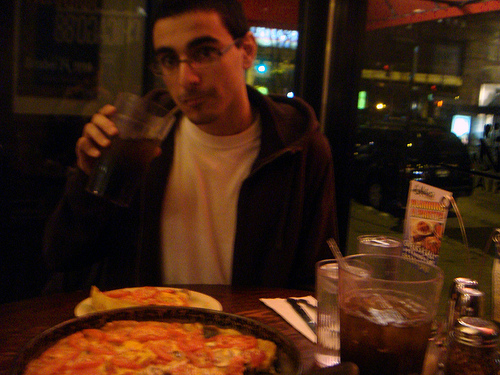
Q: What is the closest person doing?
A: Drinking.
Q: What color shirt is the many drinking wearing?
A: White.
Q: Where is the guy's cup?
A: Right hand.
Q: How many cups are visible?
A: 4.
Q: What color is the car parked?
A: Black.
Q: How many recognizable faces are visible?
A: 1.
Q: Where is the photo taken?
A: In a restaurant.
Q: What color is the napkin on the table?
A: White.